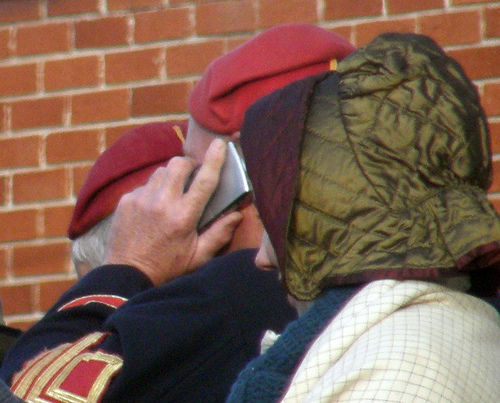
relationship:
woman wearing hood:
[229, 32, 489, 397] [292, 67, 497, 278]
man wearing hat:
[4, 26, 353, 402] [186, 19, 351, 141]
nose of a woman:
[249, 235, 276, 267] [244, 93, 431, 400]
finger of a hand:
[188, 211, 242, 269] [103, 138, 243, 284]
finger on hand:
[183, 138, 226, 228] [102, 121, 278, 332]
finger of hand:
[146, 166, 166, 191] [103, 138, 243, 284]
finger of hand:
[160, 155, 202, 193] [103, 138, 243, 284]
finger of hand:
[183, 138, 226, 228] [103, 138, 243, 284]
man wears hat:
[4, 25, 356, 396] [185, 23, 359, 134]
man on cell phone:
[4, 26, 353, 402] [183, 135, 254, 232]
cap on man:
[189, 23, 356, 133] [144, 40, 378, 319]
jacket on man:
[1, 262, 295, 401] [1, 114, 297, 401]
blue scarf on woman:
[227, 278, 364, 402] [229, 32, 489, 397]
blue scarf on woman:
[227, 284, 350, 401] [229, 32, 489, 397]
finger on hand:
[142, 159, 169, 191] [104, 130, 238, 273]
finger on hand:
[183, 138, 231, 208] [96, 133, 242, 289]